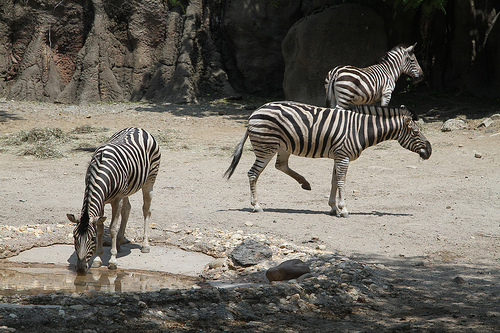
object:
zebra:
[62, 118, 172, 279]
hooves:
[247, 196, 267, 214]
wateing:
[0, 233, 235, 307]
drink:
[65, 213, 109, 282]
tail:
[215, 128, 255, 183]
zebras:
[219, 99, 442, 220]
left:
[271, 139, 315, 193]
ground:
[0, 105, 499, 331]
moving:
[296, 40, 444, 123]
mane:
[344, 100, 414, 118]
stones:
[226, 238, 274, 267]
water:
[0, 264, 200, 296]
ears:
[89, 212, 113, 230]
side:
[245, 99, 434, 163]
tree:
[1, 253, 497, 333]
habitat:
[162, 1, 497, 141]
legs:
[244, 151, 277, 216]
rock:
[1, 2, 499, 115]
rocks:
[253, 252, 315, 286]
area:
[0, 0, 500, 333]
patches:
[405, 84, 499, 141]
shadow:
[130, 0, 498, 129]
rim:
[0, 217, 366, 332]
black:
[75, 171, 94, 239]